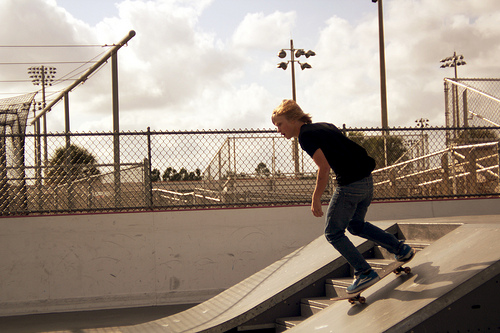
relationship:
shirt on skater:
[298, 122, 377, 187] [271, 93, 416, 291]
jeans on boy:
[319, 180, 411, 262] [271, 98, 414, 294]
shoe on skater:
[345, 268, 380, 295] [271, 93, 416, 291]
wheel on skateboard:
[358, 297, 366, 304] [341, 252, 431, 318]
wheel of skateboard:
[395, 263, 403, 271] [324, 249, 426, 306]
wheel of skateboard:
[403, 269, 413, 279] [324, 249, 426, 306]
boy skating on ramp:
[271, 98, 414, 294] [183, 205, 498, 331]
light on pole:
[277, 49, 317, 70] [286, 71, 304, 175]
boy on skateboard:
[274, 89, 424, 243] [322, 231, 426, 291]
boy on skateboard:
[271, 98, 414, 294] [334, 238, 422, 310]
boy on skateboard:
[271, 98, 414, 294] [334, 249, 418, 311]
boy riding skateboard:
[271, 98, 414, 294] [346, 252, 413, 303]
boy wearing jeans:
[271, 98, 414, 294] [323, 175, 400, 293]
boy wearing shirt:
[271, 98, 414, 294] [296, 119, 385, 187]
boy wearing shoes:
[271, 98, 414, 294] [338, 233, 415, 301]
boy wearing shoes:
[271, 98, 414, 294] [340, 241, 414, 305]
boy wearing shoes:
[271, 98, 414, 294] [339, 240, 426, 321]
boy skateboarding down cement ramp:
[271, 98, 414, 294] [105, 206, 500, 333]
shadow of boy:
[379, 260, 499, 302] [271, 98, 414, 294]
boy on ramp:
[271, 98, 414, 294] [282, 221, 499, 330]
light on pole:
[278, 46, 317, 72] [288, 37, 299, 177]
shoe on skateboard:
[393, 244, 414, 261] [331, 238, 438, 276]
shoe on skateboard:
[345, 268, 380, 295] [331, 238, 438, 276]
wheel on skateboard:
[404, 267, 411, 274] [328, 258, 407, 300]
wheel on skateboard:
[393, 266, 402, 275] [328, 258, 407, 300]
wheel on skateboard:
[355, 296, 367, 305] [328, 258, 407, 300]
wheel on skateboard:
[347, 297, 354, 304] [328, 258, 407, 300]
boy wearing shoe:
[271, 98, 414, 294] [392, 241, 415, 260]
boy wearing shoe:
[271, 98, 414, 294] [346, 263, 379, 295]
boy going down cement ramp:
[271, 98, 414, 294] [46, 212, 499, 332]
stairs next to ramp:
[275, 218, 461, 330] [126, 219, 398, 330]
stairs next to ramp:
[275, 218, 461, 330] [282, 221, 499, 330]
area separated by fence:
[237, 175, 309, 202] [202, 123, 486, 195]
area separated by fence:
[237, 175, 309, 202] [6, 162, 147, 212]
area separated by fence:
[11, 173, 93, 207] [202, 123, 486, 195]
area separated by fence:
[11, 173, 93, 207] [6, 162, 147, 212]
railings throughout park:
[0, 124, 500, 206] [5, 132, 498, 331]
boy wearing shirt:
[271, 98, 414, 294] [298, 122, 376, 187]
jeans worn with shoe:
[323, 175, 412, 275] [347, 269, 381, 295]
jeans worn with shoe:
[323, 175, 412, 275] [394, 243, 414, 260]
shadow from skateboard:
[346, 260, 434, 314] [360, 250, 397, 275]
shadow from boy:
[379, 259, 493, 302] [271, 98, 414, 294]